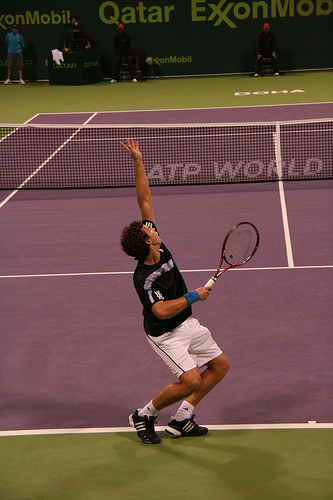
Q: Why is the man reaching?
A: He is playing tennis.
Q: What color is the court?
A: Purple.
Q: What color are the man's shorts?
A: White.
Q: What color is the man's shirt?
A: Black.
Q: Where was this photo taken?
A: On a court.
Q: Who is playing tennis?
A: The man.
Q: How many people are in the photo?
A: One.